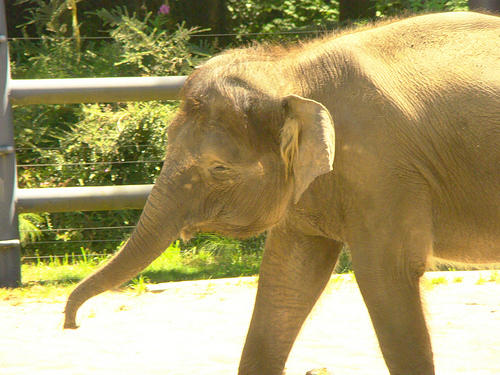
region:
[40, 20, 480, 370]
gray and brown elephant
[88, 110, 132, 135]
green leaves in brown bush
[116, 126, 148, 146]
green leaves in brown bush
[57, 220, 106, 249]
green leaves in brown bush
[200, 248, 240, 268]
green leaves in brown bush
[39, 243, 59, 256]
green leaves in brown bush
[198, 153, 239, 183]
small black eye on elephant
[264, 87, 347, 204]
brown ear on large elephant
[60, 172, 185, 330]
large brown elephant trunk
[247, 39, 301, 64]
brown hair on back of elephant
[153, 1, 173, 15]
purple flower bloom on plant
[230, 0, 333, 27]
green leaves on bushes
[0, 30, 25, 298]
silver metal fence post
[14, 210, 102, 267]
silver metal fencing wireing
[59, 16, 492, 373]
brown elephant walking beside fence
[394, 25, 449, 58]
small bumps on skin of elephant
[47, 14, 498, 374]
young gray elephant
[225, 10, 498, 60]
hair on the elephant's back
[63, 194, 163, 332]
trunk of the young elephant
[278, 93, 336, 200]
ear of the elephant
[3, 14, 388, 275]
fence behind the elephant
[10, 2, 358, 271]
foliage behind the fence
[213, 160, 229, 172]
eye of the elephant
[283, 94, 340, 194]
ear of the elephant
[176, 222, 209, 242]
mouth of the elephant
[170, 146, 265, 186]
light spots on the elephants face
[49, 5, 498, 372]
large elephant facing left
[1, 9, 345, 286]
fence enclosure behind elephant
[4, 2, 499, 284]
lush green area beyond fence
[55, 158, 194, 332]
long gray elephant trunk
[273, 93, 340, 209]
left gray elephant ear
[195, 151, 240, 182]
left eye of gray elephant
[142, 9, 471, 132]
thin hair on top of elephant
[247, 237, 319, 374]
large wrinkles in elephant leg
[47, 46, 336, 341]
large gray elephant head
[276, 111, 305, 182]
hair hanging from elephant ear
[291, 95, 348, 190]
elephants ear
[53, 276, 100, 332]
the trunk on the elephant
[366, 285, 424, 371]
the elephants left leg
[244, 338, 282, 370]
the right leg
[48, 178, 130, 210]
a pole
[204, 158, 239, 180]
left ear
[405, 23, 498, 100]
the elephants skin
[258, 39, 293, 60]
hair on the elephant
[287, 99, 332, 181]
left ear on the elephant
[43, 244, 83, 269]
the tall grass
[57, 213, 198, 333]
The trunk of an elephant.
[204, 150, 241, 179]
the eye of the elephant.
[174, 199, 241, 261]
The mouth of the elephant.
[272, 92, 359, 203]
The ear of the elephant.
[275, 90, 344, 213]
Ear of an elephant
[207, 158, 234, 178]
Eye of a elephant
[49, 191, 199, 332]
Trunk of an elephant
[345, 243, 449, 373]
Leg of an elephant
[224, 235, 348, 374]
Leg of an elephant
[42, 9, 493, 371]
Elephant inside of a pen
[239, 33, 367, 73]
hair on the elephant back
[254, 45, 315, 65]
hair on the elephant back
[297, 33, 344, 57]
hair on the elephant back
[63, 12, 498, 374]
the trunk of the baby elephant